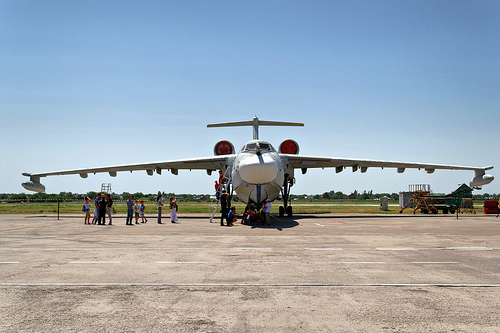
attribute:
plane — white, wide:
[22, 116, 495, 220]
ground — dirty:
[1, 215, 500, 332]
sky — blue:
[1, 1, 500, 193]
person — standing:
[169, 197, 178, 222]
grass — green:
[1, 203, 499, 216]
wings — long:
[22, 154, 496, 194]